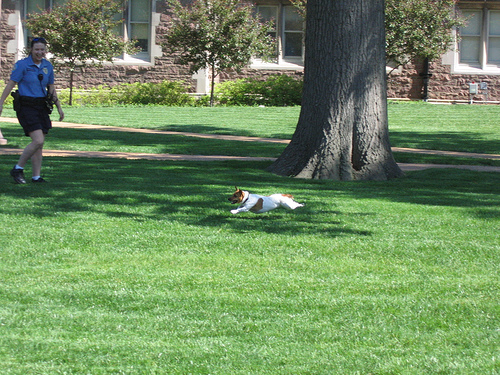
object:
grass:
[0, 106, 500, 372]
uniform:
[11, 58, 54, 137]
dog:
[228, 186, 305, 214]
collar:
[242, 195, 249, 204]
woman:
[0, 38, 65, 184]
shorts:
[14, 93, 53, 136]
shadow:
[0, 122, 499, 239]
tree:
[264, 0, 402, 180]